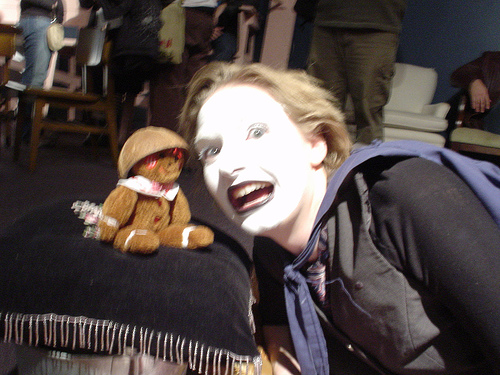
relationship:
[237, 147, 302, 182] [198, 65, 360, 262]
makeup on woman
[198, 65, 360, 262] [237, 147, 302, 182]
woman has makeup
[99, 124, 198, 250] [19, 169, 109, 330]
bear on pillow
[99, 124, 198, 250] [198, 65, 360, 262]
bear near woman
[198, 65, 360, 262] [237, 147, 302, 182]
woman wearing makeup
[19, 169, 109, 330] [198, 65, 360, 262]
pillow near woman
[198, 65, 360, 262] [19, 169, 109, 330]
woman near pillow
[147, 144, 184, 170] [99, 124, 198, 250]
eyes on bear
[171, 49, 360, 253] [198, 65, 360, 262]
hair on woman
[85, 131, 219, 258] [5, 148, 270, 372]
teddy bear on pillow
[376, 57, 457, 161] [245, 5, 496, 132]
chair by wall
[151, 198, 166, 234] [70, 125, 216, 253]
buttons on teddy bear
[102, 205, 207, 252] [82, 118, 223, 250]
lines on gingerbread man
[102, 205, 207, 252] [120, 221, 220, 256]
lines on feet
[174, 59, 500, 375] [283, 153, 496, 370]
woman wearing shirt